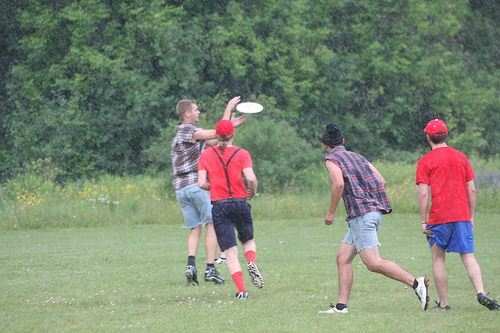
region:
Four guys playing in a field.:
[162, 92, 497, 329]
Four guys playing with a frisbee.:
[172, 93, 497, 330]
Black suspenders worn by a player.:
[204, 145, 245, 196]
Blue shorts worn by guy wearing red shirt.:
[424, 216, 478, 253]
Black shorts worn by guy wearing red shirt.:
[213, 195, 254, 248]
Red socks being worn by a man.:
[230, 249, 259, 297]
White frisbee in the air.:
[235, 99, 265, 115]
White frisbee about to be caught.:
[235, 100, 266, 115]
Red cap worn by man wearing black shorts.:
[215, 120, 233, 137]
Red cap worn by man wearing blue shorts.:
[422, 117, 449, 137]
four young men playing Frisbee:
[171, 94, 485, 302]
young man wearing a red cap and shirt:
[412, 115, 499, 317]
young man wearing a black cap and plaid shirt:
[310, 126, 430, 316]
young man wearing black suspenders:
[195, 116, 268, 301]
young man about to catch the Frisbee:
[167, 95, 264, 291]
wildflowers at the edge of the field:
[0, 154, 174, 236]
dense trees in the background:
[12, 4, 499, 91]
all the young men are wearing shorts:
[166, 97, 499, 314]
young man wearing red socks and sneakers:
[193, 118, 265, 303]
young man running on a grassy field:
[315, 124, 429, 317]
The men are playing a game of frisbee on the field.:
[150, 60, 497, 316]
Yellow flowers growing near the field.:
[3, 172, 149, 208]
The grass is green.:
[3, 236, 158, 284]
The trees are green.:
[1, 0, 149, 166]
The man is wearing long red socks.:
[221, 242, 271, 302]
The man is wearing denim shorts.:
[340, 207, 390, 253]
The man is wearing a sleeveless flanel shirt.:
[323, 148, 398, 223]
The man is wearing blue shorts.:
[423, 220, 478, 256]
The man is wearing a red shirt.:
[197, 135, 253, 203]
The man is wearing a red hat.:
[420, 113, 451, 137]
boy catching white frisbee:
[157, 79, 302, 293]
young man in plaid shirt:
[308, 122, 430, 315]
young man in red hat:
[405, 112, 499, 314]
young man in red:
[192, 111, 271, 302]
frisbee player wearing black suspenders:
[189, 86, 279, 312]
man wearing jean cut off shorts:
[310, 112, 428, 332]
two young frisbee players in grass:
[150, 89, 294, 311]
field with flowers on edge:
[8, 144, 144, 276]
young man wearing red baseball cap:
[401, 99, 496, 289]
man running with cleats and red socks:
[185, 88, 285, 305]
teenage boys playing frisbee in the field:
[170, 95, 497, 310]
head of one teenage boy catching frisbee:
[179, 101, 199, 124]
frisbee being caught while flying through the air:
[235, 99, 262, 114]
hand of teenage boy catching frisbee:
[226, 95, 238, 110]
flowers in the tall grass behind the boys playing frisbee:
[14, 187, 157, 204]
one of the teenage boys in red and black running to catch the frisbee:
[200, 120, 262, 295]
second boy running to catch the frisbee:
[316, 123, 413, 316]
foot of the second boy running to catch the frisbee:
[411, 275, 429, 310]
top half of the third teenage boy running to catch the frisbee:
[413, 118, 477, 225]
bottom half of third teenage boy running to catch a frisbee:
[431, 218, 498, 313]